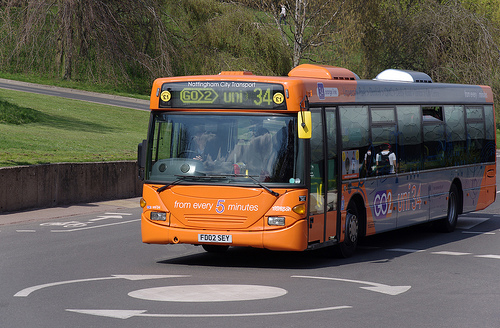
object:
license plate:
[197, 233, 234, 243]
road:
[0, 155, 499, 327]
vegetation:
[228, 0, 344, 68]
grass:
[0, 87, 168, 167]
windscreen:
[148, 113, 294, 185]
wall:
[0, 160, 143, 215]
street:
[0, 78, 151, 112]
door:
[324, 106, 342, 242]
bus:
[137, 64, 497, 258]